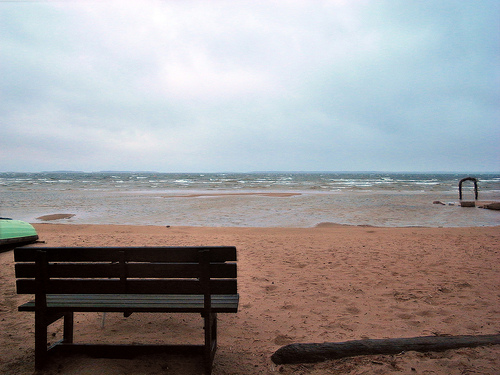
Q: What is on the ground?
A: Bench.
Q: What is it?
A: Beach.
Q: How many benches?
A: 1.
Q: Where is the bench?
A: On the sand.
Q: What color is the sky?
A: Blue.